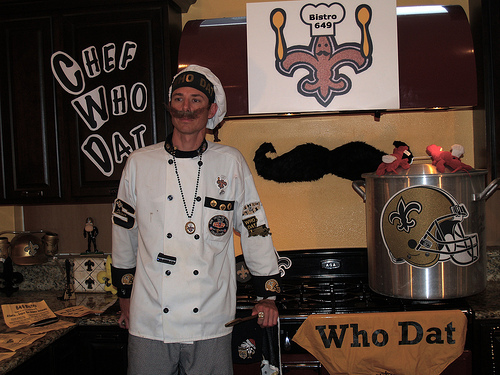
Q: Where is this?
A: This is at the kitchen.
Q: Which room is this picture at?
A: It is at the kitchen.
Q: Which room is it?
A: It is a kitchen.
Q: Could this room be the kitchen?
A: Yes, it is the kitchen.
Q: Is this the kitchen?
A: Yes, it is the kitchen.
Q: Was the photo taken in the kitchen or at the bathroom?
A: It was taken at the kitchen.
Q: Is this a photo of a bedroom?
A: No, the picture is showing a kitchen.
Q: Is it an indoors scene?
A: Yes, it is indoors.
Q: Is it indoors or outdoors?
A: It is indoors.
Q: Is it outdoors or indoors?
A: It is indoors.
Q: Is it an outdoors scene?
A: No, it is indoors.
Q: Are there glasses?
A: No, there are no glasses.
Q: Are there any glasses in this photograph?
A: No, there are no glasses.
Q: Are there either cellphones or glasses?
A: No, there are no glasses or cellphones.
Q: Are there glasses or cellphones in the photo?
A: No, there are no glasses or cellphones.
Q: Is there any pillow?
A: No, there are no pillows.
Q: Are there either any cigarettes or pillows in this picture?
A: No, there are no pillows or cigarettes.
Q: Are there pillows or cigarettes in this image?
A: No, there are no pillows or cigarettes.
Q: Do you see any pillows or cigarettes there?
A: No, there are no pillows or cigarettes.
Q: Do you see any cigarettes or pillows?
A: No, there are no pillows or cigarettes.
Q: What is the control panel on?
A: The control panel is on the stove.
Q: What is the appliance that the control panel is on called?
A: The appliance is a stove.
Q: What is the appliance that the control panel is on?
A: The appliance is a stove.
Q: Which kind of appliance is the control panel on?
A: The control panel is on the stove.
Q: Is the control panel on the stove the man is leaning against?
A: Yes, the control panel is on the stove.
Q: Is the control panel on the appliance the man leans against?
A: Yes, the control panel is on the stove.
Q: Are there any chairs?
A: No, there are no chairs.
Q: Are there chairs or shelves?
A: No, there are no chairs or shelves.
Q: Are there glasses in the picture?
A: No, there are no glasses.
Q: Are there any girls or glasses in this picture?
A: No, there are no glasses or girls.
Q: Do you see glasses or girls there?
A: No, there are no glasses or girls.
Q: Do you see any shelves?
A: No, there are no shelves.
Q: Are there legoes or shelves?
A: No, there are no shelves or legoes.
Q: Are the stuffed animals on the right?
A: Yes, the stuffed animals are on the right of the image.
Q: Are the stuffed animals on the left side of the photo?
A: No, the stuffed animals are on the right of the image.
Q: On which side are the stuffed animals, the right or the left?
A: The stuffed animals are on the right of the image.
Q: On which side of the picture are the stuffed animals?
A: The stuffed animals are on the right of the image.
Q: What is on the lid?
A: The stuffed animals are on the lid.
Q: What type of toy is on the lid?
A: The toys are stuffed animals.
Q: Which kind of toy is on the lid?
A: The toys are stuffed animals.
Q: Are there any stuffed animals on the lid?
A: Yes, there are stuffed animals on the lid.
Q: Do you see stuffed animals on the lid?
A: Yes, there are stuffed animals on the lid.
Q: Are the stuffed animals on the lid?
A: Yes, the stuffed animals are on the lid.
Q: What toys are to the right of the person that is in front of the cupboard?
A: The toys are stuffed animals.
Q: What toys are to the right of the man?
A: The toys are stuffed animals.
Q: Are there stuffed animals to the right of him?
A: Yes, there are stuffed animals to the right of the man.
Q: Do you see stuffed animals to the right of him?
A: Yes, there are stuffed animals to the right of the man.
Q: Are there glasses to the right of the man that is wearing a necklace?
A: No, there are stuffed animals to the right of the man.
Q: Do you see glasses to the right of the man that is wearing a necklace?
A: No, there are stuffed animals to the right of the man.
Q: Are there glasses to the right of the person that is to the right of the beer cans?
A: No, there are stuffed animals to the right of the man.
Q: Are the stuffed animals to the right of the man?
A: Yes, the stuffed animals are to the right of the man.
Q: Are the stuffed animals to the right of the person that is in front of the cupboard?
A: Yes, the stuffed animals are to the right of the man.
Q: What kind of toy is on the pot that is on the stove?
A: The toys are stuffed animals.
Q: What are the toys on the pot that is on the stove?
A: The toys are stuffed animals.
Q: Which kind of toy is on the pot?
A: The toys are stuffed animals.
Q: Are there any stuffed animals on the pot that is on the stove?
A: Yes, there are stuffed animals on the pot.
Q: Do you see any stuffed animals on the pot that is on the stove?
A: Yes, there are stuffed animals on the pot.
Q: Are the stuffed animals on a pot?
A: Yes, the stuffed animals are on a pot.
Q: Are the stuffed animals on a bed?
A: No, the stuffed animals are on a pot.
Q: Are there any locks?
A: No, there are no locks.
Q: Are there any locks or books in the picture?
A: No, there are no locks or books.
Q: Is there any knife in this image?
A: Yes, there is a knife.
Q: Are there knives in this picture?
A: Yes, there is a knife.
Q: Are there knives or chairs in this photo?
A: Yes, there is a knife.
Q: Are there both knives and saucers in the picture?
A: No, there is a knife but no saucers.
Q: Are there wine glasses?
A: No, there are no wine glasses.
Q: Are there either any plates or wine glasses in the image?
A: No, there are no wine glasses or plates.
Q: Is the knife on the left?
A: Yes, the knife is on the left of the image.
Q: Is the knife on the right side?
A: No, the knife is on the left of the image.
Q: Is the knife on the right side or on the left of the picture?
A: The knife is on the left of the image.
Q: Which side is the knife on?
A: The knife is on the left of the image.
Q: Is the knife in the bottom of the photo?
A: Yes, the knife is in the bottom of the image.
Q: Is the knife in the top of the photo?
A: No, the knife is in the bottom of the image.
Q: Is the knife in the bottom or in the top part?
A: The knife is in the bottom of the image.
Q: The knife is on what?
A: The knife is on the counter.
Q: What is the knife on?
A: The knife is on the counter.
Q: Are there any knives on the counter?
A: Yes, there is a knife on the counter.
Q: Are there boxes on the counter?
A: No, there is a knife on the counter.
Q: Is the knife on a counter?
A: Yes, the knife is on a counter.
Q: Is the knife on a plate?
A: No, the knife is on a counter.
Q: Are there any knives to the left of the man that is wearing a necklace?
A: Yes, there is a knife to the left of the man.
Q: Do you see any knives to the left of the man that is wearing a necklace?
A: Yes, there is a knife to the left of the man.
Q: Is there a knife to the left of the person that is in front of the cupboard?
A: Yes, there is a knife to the left of the man.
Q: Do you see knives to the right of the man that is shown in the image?
A: No, the knife is to the left of the man.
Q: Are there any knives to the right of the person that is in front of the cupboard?
A: No, the knife is to the left of the man.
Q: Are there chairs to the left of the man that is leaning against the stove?
A: No, there is a knife to the left of the man.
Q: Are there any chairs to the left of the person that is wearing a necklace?
A: No, there is a knife to the left of the man.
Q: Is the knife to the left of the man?
A: Yes, the knife is to the left of the man.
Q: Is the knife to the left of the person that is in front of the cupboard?
A: Yes, the knife is to the left of the man.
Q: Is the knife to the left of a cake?
A: No, the knife is to the left of the man.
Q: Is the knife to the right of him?
A: No, the knife is to the left of the man.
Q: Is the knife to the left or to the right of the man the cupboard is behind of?
A: The knife is to the left of the man.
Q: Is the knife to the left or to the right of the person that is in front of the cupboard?
A: The knife is to the left of the man.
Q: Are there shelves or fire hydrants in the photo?
A: No, there are no shelves or fire hydrants.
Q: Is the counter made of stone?
A: No, the counter is made of marble.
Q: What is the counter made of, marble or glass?
A: The counter is made of marble.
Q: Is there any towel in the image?
A: Yes, there is a towel.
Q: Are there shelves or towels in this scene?
A: Yes, there is a towel.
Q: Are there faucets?
A: No, there are no faucets.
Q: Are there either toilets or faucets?
A: No, there are no faucets or toilets.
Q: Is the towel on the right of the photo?
A: Yes, the towel is on the right of the image.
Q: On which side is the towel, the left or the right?
A: The towel is on the right of the image.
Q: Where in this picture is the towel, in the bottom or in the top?
A: The towel is in the bottom of the image.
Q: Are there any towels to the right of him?
A: Yes, there is a towel to the right of the man.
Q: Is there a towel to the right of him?
A: Yes, there is a towel to the right of the man.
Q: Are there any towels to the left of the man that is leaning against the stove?
A: No, the towel is to the right of the man.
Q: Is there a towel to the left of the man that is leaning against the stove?
A: No, the towel is to the right of the man.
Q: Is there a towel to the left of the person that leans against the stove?
A: No, the towel is to the right of the man.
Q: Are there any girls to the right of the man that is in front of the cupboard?
A: No, there is a towel to the right of the man.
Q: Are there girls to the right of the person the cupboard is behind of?
A: No, there is a towel to the right of the man.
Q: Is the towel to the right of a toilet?
A: No, the towel is to the right of a man.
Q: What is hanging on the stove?
A: The towel is hanging on the stove.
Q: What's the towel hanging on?
A: The towel is hanging on the stove.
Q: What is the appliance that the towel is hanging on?
A: The appliance is a stove.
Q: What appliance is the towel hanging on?
A: The towel is hanging on the stove.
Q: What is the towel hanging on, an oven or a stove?
A: The towel is hanging on a stove.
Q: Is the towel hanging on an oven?
A: No, the towel is hanging on a stove.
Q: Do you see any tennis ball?
A: No, there are no tennis balls.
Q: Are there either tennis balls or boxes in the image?
A: No, there are no tennis balls or boxes.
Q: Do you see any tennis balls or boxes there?
A: No, there are no tennis balls or boxes.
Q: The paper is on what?
A: The paper is on the counter.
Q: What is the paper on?
A: The paper is on the counter.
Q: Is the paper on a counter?
A: Yes, the paper is on a counter.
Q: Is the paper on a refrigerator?
A: No, the paper is on a counter.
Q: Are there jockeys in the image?
A: No, there are no jockeys.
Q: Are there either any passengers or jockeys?
A: No, there are no jockeys or passengers.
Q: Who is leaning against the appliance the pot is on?
A: The man is leaning against the stove.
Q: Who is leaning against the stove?
A: The man is leaning against the stove.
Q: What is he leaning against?
A: The man is leaning against the stove.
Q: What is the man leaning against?
A: The man is leaning against the stove.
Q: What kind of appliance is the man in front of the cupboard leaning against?
A: The man is leaning against the stove.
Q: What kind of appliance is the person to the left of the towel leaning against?
A: The man is leaning against the stove.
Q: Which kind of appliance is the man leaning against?
A: The man is leaning against the stove.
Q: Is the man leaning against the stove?
A: Yes, the man is leaning against the stove.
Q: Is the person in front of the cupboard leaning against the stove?
A: Yes, the man is leaning against the stove.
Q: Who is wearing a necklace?
A: The man is wearing a necklace.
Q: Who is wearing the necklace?
A: The man is wearing a necklace.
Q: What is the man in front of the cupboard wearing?
A: The man is wearing a necklace.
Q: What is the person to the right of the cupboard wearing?
A: The man is wearing a necklace.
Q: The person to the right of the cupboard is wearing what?
A: The man is wearing a necklace.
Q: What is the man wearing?
A: The man is wearing a necklace.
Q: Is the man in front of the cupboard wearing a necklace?
A: Yes, the man is wearing a necklace.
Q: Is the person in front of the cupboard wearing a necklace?
A: Yes, the man is wearing a necklace.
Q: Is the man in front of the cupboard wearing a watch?
A: No, the man is wearing a necklace.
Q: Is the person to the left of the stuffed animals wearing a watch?
A: No, the man is wearing a necklace.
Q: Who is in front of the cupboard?
A: The man is in front of the cupboard.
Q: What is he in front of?
A: The man is in front of the cupboard.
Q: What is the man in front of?
A: The man is in front of the cupboard.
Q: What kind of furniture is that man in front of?
A: The man is in front of the cupboard.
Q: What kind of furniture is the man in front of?
A: The man is in front of the cupboard.